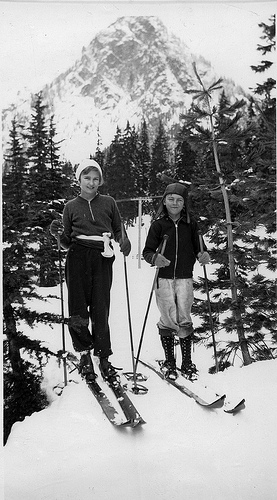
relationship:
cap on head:
[71, 152, 108, 184] [53, 145, 147, 368]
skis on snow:
[53, 342, 250, 428] [0, 215, 275, 498]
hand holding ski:
[146, 243, 185, 282] [116, 233, 176, 387]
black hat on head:
[153, 184, 190, 224] [157, 191, 191, 219]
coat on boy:
[152, 221, 195, 276] [141, 181, 210, 381]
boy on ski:
[50, 158, 131, 376] [60, 345, 157, 437]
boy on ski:
[141, 181, 210, 381] [129, 339, 276, 415]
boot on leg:
[157, 328, 177, 381] [154, 276, 174, 362]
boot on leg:
[178, 333, 199, 379] [174, 279, 194, 363]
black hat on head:
[153, 178, 196, 225] [163, 188, 185, 215]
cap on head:
[74, 158, 104, 185] [77, 163, 99, 193]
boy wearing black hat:
[141, 181, 210, 381] [153, 184, 190, 224]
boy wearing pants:
[50, 158, 131, 376] [61, 243, 123, 363]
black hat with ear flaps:
[153, 184, 190, 224] [146, 204, 193, 221]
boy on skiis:
[51, 147, 132, 377] [70, 356, 144, 431]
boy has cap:
[141, 181, 210, 381] [152, 180, 195, 223]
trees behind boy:
[102, 123, 155, 181] [50, 158, 131, 376]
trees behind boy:
[102, 123, 155, 181] [141, 181, 210, 381]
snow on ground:
[0, 215, 275, 498] [12, 419, 275, 498]